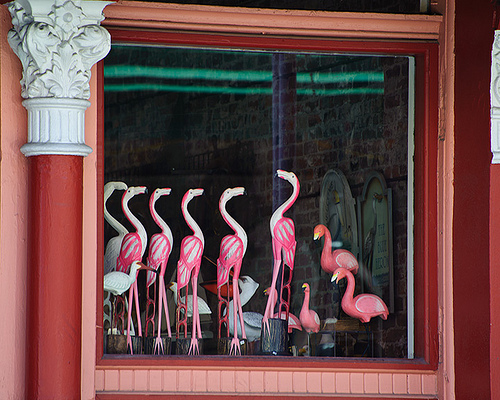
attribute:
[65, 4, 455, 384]
window — for display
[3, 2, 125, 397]
column — red, white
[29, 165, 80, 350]
column — red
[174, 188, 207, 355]
fake flamingo — pink, white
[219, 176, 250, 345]
fake flamingo — white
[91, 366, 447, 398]
brick — pink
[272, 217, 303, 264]
wing — white, pink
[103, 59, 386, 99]
reflection — green